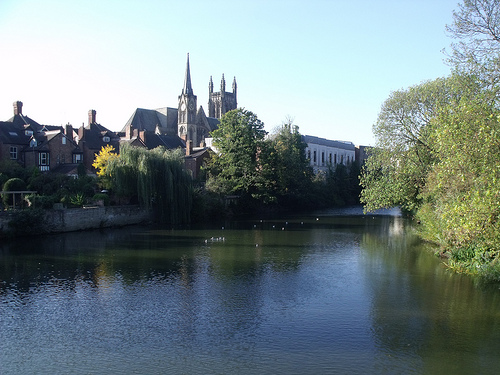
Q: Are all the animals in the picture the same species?
A: Yes, all the animals are birds.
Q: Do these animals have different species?
A: No, all the animals are birds.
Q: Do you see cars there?
A: No, there are no cars.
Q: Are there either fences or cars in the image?
A: No, there are no cars or fences.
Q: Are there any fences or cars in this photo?
A: No, there are no cars or fences.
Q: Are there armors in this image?
A: No, there are no armors.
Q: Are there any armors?
A: No, there are no armors.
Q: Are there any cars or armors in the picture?
A: No, there are no armors or cars.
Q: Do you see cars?
A: No, there are no cars.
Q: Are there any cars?
A: No, there are no cars.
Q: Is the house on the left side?
A: Yes, the house is on the left of the image.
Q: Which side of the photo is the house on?
A: The house is on the left of the image.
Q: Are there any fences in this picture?
A: No, there are no fences.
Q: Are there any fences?
A: No, there are no fences.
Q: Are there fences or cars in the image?
A: No, there are no fences or cars.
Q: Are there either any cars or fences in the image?
A: No, there are no fences or cars.